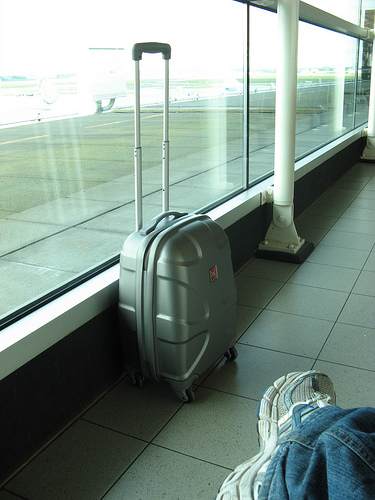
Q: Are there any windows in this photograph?
A: Yes, there are windows.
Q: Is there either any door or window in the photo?
A: Yes, there are windows.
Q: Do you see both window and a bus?
A: No, there are windows but no buses.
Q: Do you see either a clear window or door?
A: Yes, there are clear windows.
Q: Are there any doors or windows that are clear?
A: Yes, the windows are clear.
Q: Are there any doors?
A: No, there are no doors.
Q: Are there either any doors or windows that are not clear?
A: No, there are windows but they are clear.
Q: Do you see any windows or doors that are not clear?
A: No, there are windows but they are clear.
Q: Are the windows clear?
A: Yes, the windows are clear.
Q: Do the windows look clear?
A: Yes, the windows are clear.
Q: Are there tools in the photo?
A: No, there are no tools.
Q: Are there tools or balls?
A: No, there are no tools or balls.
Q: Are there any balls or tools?
A: No, there are no tools or balls.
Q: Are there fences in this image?
A: No, there are no fences.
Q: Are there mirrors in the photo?
A: No, there are no mirrors.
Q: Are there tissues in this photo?
A: No, there are no tissues.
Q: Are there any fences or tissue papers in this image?
A: No, there are no tissue papers or fences.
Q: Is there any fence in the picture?
A: No, there are no fences.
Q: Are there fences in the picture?
A: No, there are no fences.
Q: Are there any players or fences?
A: No, there are no fences or players.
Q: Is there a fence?
A: No, there are no fences.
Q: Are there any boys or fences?
A: No, there are no fences or boys.